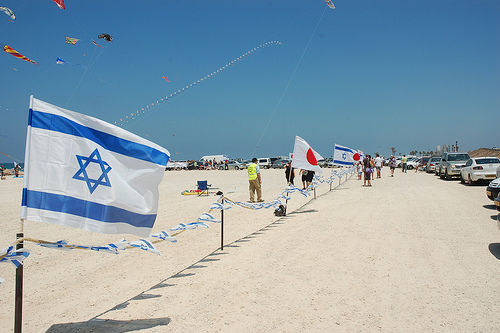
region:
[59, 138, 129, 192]
blue and white star on flag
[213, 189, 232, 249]
black post on ground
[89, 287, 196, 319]
shadow on the sand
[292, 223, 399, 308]
clean sand on the ground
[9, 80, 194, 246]
large flag on pole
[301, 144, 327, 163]
red circle on flag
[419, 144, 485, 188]
cars on side of the sand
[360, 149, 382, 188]
people standing on the sand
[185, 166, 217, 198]
blue chair on the sand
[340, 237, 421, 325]
a beach full of sand.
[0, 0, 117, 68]
a bunch of different color kites.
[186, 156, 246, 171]
a bunch of people are standing beside vehicles.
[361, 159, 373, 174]
a man is carrying a grey shoulder bag.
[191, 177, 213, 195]
a small blue beach chair.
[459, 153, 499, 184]
a white car is parked on the beach.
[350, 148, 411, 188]
a bunch of people are walking on the beach.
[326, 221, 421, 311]
Large body of sand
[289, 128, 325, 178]
White and red flag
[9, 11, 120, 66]
Kites in the sky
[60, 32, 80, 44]
A kite in the sky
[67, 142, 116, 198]
Star on a flag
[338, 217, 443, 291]
Body of sand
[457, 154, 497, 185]
White car to the right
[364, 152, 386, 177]
Group of people walking together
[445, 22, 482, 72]
a clear blue sky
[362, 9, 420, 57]
a clear blue sky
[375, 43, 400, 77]
a clear blue sky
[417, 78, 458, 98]
a clear blue sky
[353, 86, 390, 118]
a clear blue sky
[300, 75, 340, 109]
a clear blue sky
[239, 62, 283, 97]
a clear blue sky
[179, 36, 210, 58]
a clear blue sky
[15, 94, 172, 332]
A flag on the sand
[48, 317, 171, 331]
A shadow on the sand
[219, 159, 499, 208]
Vehicles parked on the sand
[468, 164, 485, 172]
A tail light on the car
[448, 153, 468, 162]
The windshield of the car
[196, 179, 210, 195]
A chair on the sand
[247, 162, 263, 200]
A man standing by a flag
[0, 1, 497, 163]
The sky above the kites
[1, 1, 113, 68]
Kites above the beach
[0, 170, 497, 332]
Sand at the beach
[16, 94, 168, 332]
an Israeli flag on a pole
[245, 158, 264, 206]
a man in a yellow shirt on a beach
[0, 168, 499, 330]
a sandy beach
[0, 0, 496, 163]
a clear blue sky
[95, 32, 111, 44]
a kite in the sky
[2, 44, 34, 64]
a kite inthe sky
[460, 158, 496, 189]
a parked white car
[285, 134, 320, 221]
a flag on a pole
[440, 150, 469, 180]
a silver SUV on a beach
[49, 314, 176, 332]
a flag shadow on the sand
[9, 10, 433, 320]
international flags on beach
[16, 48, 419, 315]
various country flags on beach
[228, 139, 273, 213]
man in neon vest standing on beach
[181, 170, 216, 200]
blue beach chair set up on sand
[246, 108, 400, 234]
japanese and israeli flags at beach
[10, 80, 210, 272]
blue and white flag with star of david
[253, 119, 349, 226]
red and white flag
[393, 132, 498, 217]
line of cars parked at beach